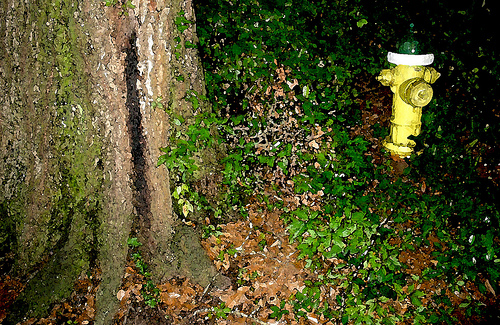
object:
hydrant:
[373, 21, 442, 158]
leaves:
[271, 29, 281, 35]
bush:
[288, 201, 373, 261]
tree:
[2, 0, 272, 323]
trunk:
[0, 0, 244, 216]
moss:
[44, 0, 88, 248]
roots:
[91, 238, 128, 325]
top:
[386, 29, 434, 66]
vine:
[128, 235, 159, 307]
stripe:
[385, 51, 436, 64]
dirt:
[120, 303, 176, 324]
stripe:
[121, 35, 150, 220]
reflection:
[411, 47, 415, 53]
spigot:
[403, 81, 436, 107]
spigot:
[375, 68, 391, 87]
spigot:
[427, 67, 442, 82]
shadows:
[399, 132, 495, 191]